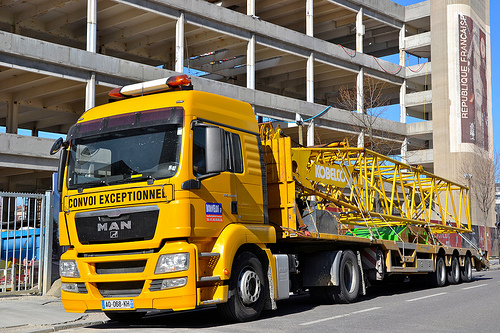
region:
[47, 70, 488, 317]
the yellow truck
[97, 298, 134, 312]
the license plate on the front of the truck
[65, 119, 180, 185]
the windshield on the truck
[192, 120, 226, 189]
the driver's side mirror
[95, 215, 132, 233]
the word MAN on the front of the bus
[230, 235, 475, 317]
the wheels on the driver's side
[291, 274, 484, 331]
the white lines on the road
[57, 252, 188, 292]
the lights on the front of the truck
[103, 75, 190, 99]
the lights on the top of the truck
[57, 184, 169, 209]
the black letters on the front of the truck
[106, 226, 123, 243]
logo on front of truck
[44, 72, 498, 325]
large yellow truck parked on side of road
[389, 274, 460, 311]
white line painted on street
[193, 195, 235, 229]
blue and red sticker on door of truck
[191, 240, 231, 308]
grey metal stairs on side of truck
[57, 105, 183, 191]
large wind shield on truck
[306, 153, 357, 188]
white text on side of truck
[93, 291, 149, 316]
license plate on front of truck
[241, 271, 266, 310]
grey metal hub-cap on truck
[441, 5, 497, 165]
large sign hanging on side of building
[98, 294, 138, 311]
license plate on front of truck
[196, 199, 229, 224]
blue and red sticker on side of truck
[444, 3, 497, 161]
large sign on side of building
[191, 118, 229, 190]
large metal side mirror on truck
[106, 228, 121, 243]
logo on grill of truck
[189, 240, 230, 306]
grey metal steps on side of truck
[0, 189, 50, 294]
grey metal fencing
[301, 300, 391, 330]
white lines painted on road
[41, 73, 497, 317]
large truck parked on side of street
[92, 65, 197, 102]
large safety lights on cab of truck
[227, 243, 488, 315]
tires on truck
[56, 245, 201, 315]
front grill on yellow truck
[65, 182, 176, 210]
lettering on front of yellow truck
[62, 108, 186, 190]
windshield on yellow truck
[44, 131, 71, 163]
sideview mirror on truck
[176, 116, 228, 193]
sideview mirror on yellow truck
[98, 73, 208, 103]
safety light on yellow truck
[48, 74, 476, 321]
large yellow truck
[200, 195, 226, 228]
sign on door of yellow truck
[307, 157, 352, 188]
sign on side of yellow truck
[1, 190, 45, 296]
A metal gate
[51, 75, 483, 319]
A large yellow truck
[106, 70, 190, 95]
lights on top of a truck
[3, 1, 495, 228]
A parking deck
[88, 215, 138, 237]
branding on the truck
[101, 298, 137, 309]
the front license plate of the truck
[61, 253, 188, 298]
headlights on the truck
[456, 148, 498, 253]
A leafless tree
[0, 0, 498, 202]
A clear, blue sky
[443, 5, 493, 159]
an advertisement